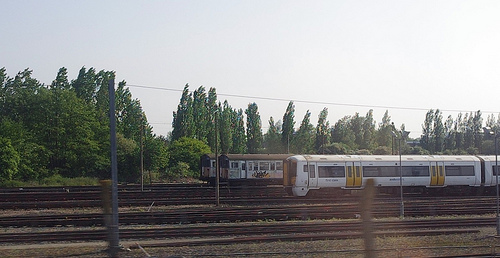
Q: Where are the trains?
A: On tracks.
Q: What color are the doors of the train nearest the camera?
A: Yellow.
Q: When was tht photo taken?
A: Daytime.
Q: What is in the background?
A: Trees.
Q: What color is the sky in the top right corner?
A: White.